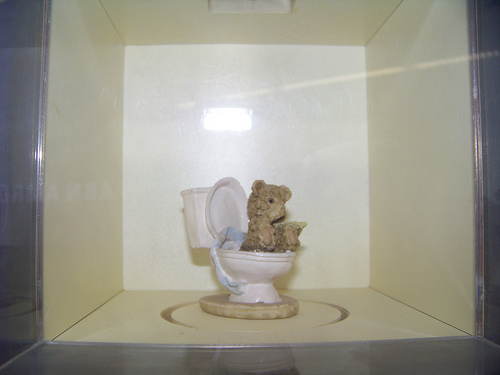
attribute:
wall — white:
[1, 2, 478, 367]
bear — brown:
[240, 179, 308, 255]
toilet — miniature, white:
[169, 171, 301, 308]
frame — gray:
[14, 2, 488, 367]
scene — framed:
[39, 5, 481, 354]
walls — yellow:
[49, 4, 472, 368]